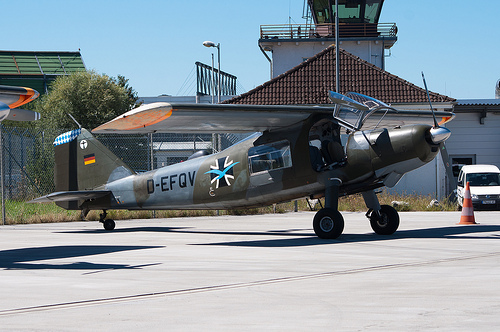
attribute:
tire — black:
[309, 207, 344, 242]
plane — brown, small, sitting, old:
[58, 87, 460, 244]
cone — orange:
[449, 181, 485, 226]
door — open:
[306, 129, 343, 168]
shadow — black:
[254, 224, 329, 255]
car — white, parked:
[458, 159, 500, 213]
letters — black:
[149, 171, 194, 198]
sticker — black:
[81, 150, 101, 166]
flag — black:
[81, 155, 98, 168]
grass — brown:
[382, 195, 439, 211]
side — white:
[449, 114, 494, 149]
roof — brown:
[244, 51, 425, 112]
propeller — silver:
[406, 74, 481, 186]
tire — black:
[369, 207, 400, 230]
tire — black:
[101, 218, 122, 235]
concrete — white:
[403, 214, 488, 283]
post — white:
[336, 12, 337, 93]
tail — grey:
[47, 135, 111, 194]